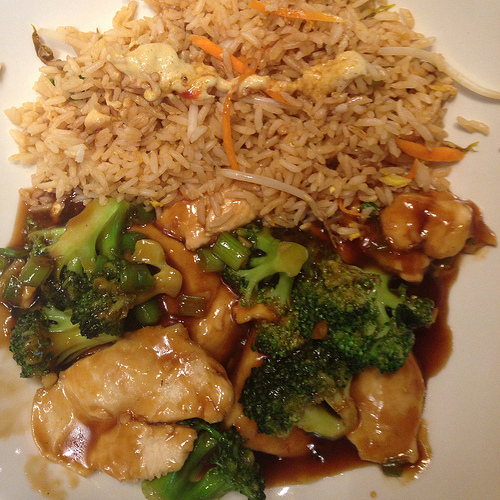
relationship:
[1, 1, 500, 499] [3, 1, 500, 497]
plate of chinese food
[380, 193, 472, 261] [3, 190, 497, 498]
chicken has sauce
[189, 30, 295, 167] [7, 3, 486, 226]
carrots in rice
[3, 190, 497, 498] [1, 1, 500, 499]
sauce on plate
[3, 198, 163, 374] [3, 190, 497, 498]
broccoli pieces has sauce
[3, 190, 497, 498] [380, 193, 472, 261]
sauce on chicken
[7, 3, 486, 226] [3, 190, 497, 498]
rice has sauce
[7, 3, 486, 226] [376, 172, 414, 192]
rice has something yellow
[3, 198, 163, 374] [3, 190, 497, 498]
broccoli pieces has brown sauce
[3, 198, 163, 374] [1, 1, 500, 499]
broccoli pieces are on plate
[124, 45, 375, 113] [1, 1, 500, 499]
meat on plate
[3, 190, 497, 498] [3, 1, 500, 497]
sauce on food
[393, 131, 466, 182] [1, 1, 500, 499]
pieces of carrot are on plate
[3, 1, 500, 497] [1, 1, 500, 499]
food on plate